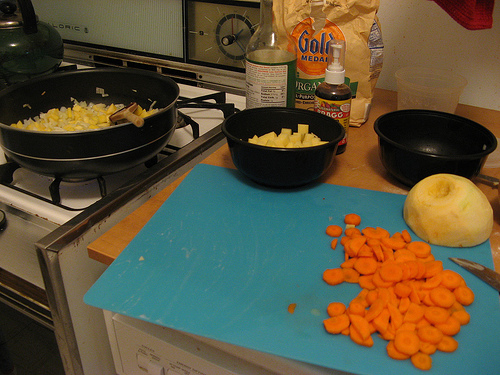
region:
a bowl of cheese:
[169, 37, 370, 192]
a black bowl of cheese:
[239, 61, 349, 191]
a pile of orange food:
[297, 211, 447, 362]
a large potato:
[377, 152, 499, 236]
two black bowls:
[221, 41, 499, 198]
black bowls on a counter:
[211, 38, 468, 233]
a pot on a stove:
[9, 23, 264, 281]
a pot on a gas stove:
[21, 17, 232, 244]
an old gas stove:
[8, 10, 256, 234]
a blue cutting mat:
[168, 114, 412, 371]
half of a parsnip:
[400, 170, 496, 250]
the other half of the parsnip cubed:
[245, 121, 329, 148]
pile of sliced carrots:
[320, 213, 475, 371]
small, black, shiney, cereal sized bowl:
[371, 106, 498, 191]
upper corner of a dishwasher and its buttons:
[100, 307, 358, 373]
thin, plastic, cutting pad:
[80, 159, 498, 373]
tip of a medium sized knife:
[447, 254, 499, 291]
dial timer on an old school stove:
[179, 0, 264, 73]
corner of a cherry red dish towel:
[432, 0, 494, 29]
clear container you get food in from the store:
[392, 64, 467, 115]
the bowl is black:
[131, 72, 331, 242]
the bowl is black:
[210, 70, 370, 327]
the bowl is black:
[211, 114, 321, 214]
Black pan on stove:
[0, 59, 188, 236]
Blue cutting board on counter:
[90, 156, 335, 363]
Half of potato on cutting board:
[388, 169, 497, 256]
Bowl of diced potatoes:
[220, 99, 348, 203]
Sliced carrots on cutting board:
[299, 202, 474, 367]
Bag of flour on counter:
[263, 0, 379, 127]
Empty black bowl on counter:
[368, 104, 498, 191]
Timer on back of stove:
[173, 5, 271, 87]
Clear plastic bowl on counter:
[383, 55, 475, 126]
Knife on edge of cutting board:
[445, 249, 499, 304]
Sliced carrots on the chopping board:
[286, 202, 485, 363]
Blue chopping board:
[160, 226, 401, 331]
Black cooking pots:
[7, 75, 477, 185]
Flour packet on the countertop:
[272, 2, 381, 113]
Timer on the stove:
[187, 4, 262, 70]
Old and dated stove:
[7, 22, 252, 281]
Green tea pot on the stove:
[0, 7, 71, 79]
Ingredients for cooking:
[242, 10, 368, 124]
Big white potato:
[393, 164, 496, 251]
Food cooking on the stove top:
[0, 66, 177, 181]